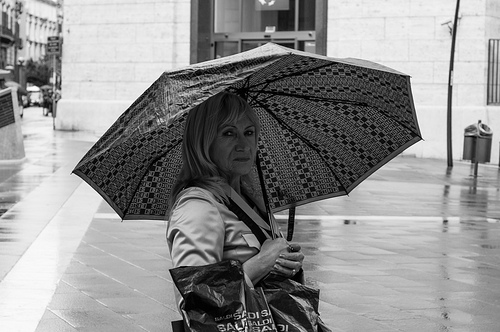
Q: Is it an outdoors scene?
A: Yes, it is outdoors.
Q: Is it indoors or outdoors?
A: It is outdoors.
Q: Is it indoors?
A: No, it is outdoors.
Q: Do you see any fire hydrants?
A: No, there are no fire hydrants.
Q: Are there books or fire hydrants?
A: No, there are no fire hydrants or books.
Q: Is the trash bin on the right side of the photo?
A: Yes, the trash bin is on the right of the image.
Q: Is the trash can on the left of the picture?
A: No, the trash can is on the right of the image.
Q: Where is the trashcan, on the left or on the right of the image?
A: The trashcan is on the right of the image.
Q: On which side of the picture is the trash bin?
A: The trash bin is on the right of the image.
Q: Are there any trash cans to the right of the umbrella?
A: Yes, there is a trash can to the right of the umbrella.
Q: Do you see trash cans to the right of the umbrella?
A: Yes, there is a trash can to the right of the umbrella.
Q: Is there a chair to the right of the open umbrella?
A: No, there is a trash can to the right of the umbrella.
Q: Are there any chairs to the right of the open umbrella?
A: No, there is a trash can to the right of the umbrella.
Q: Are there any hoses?
A: No, there are no hoses.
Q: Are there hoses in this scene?
A: No, there are no hoses.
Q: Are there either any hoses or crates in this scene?
A: No, there are no hoses or crates.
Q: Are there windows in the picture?
A: Yes, there is a window.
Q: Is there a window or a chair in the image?
A: Yes, there is a window.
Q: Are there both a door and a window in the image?
A: Yes, there are both a window and a door.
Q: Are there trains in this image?
A: No, there are no trains.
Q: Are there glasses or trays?
A: No, there are no glasses or trays.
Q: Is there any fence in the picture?
A: No, there are no fences.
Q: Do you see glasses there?
A: No, there are no glasses.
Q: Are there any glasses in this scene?
A: No, there are no glasses.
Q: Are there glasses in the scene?
A: No, there are no glasses.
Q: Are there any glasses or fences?
A: No, there are no glasses or fences.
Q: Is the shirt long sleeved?
A: Yes, the shirt is long sleeved.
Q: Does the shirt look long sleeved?
A: Yes, the shirt is long sleeved.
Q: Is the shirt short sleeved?
A: No, the shirt is long sleeved.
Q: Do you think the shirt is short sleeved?
A: No, the shirt is long sleeved.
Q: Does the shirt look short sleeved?
A: No, the shirt is long sleeved.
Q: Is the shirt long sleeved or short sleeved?
A: The shirt is long sleeved.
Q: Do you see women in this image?
A: Yes, there is a woman.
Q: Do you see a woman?
A: Yes, there is a woman.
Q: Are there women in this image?
A: Yes, there is a woman.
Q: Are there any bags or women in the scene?
A: Yes, there is a woman.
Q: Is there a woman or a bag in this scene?
A: Yes, there is a woman.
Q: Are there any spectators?
A: No, there are no spectators.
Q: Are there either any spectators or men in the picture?
A: No, there are no spectators or men.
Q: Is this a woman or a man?
A: This is a woman.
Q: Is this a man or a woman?
A: This is a woman.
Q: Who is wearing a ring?
A: The woman is wearing a ring.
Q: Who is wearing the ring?
A: The woman is wearing a ring.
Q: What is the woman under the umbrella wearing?
A: The woman is wearing a ring.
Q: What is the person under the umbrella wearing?
A: The woman is wearing a ring.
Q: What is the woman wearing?
A: The woman is wearing a ring.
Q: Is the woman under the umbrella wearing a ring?
A: Yes, the woman is wearing a ring.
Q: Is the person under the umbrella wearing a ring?
A: Yes, the woman is wearing a ring.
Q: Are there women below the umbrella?
A: Yes, there is a woman below the umbrella.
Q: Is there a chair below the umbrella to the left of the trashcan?
A: No, there is a woman below the umbrella.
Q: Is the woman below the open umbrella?
A: Yes, the woman is below the umbrella.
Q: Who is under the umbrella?
A: The woman is under the umbrella.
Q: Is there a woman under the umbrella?
A: Yes, there is a woman under the umbrella.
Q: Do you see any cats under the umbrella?
A: No, there is a woman under the umbrella.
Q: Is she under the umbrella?
A: Yes, the woman is under the umbrella.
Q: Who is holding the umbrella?
A: The woman is holding the umbrella.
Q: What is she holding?
A: The woman is holding the umbrella.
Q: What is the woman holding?
A: The woman is holding the umbrella.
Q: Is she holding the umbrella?
A: Yes, the woman is holding the umbrella.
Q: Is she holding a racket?
A: No, the woman is holding the umbrella.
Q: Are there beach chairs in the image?
A: No, there are no beach chairs.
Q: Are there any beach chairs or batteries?
A: No, there are no beach chairs or batteries.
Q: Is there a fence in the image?
A: No, there are no fences.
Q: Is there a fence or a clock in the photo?
A: No, there are no fences or clocks.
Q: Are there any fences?
A: No, there are no fences.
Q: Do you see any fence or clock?
A: No, there are no fences or clocks.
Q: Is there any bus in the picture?
A: No, there are no buses.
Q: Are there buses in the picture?
A: No, there are no buses.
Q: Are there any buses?
A: No, there are no buses.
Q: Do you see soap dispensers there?
A: No, there are no soap dispensers.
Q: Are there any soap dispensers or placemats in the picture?
A: No, there are no soap dispensers or placemats.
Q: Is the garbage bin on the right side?
A: Yes, the garbage bin is on the right of the image.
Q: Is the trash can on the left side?
A: No, the trash can is on the right of the image.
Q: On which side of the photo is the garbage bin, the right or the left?
A: The garbage bin is on the right of the image.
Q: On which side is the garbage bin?
A: The garbage bin is on the right of the image.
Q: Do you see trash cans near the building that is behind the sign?
A: Yes, there is a trash can near the building.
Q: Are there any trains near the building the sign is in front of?
A: No, there is a trash can near the building.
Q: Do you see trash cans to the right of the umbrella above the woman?
A: Yes, there is a trash can to the right of the umbrella.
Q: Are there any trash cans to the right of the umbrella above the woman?
A: Yes, there is a trash can to the right of the umbrella.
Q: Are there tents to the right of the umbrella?
A: No, there is a trash can to the right of the umbrella.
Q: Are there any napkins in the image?
A: No, there are no napkins.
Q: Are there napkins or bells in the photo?
A: No, there are no napkins or bells.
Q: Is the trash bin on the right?
A: Yes, the trash bin is on the right of the image.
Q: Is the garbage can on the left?
A: No, the garbage can is on the right of the image.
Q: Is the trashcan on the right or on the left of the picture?
A: The trashcan is on the right of the image.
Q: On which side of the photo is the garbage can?
A: The garbage can is on the right of the image.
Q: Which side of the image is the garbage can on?
A: The garbage can is on the right of the image.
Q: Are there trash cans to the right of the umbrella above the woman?
A: Yes, there is a trash can to the right of the umbrella.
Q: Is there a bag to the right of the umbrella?
A: No, there is a trash can to the right of the umbrella.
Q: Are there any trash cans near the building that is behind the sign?
A: Yes, there is a trash can near the building.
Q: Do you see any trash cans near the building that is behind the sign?
A: Yes, there is a trash can near the building.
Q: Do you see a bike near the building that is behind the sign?
A: No, there is a trash can near the building.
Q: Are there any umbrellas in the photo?
A: Yes, there is an umbrella.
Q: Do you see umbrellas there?
A: Yes, there is an umbrella.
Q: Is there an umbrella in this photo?
A: Yes, there is an umbrella.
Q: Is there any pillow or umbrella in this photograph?
A: Yes, there is an umbrella.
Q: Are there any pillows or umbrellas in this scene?
A: Yes, there is an umbrella.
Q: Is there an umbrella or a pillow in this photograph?
A: Yes, there is an umbrella.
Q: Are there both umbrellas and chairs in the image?
A: No, there is an umbrella but no chairs.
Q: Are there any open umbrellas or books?
A: Yes, there is an open umbrella.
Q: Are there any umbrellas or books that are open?
A: Yes, the umbrella is open.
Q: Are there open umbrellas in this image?
A: Yes, there is an open umbrella.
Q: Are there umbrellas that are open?
A: Yes, there is an umbrella that is open.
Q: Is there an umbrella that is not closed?
A: Yes, there is a open umbrella.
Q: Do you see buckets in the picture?
A: No, there are no buckets.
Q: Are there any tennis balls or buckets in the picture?
A: No, there are no buckets or tennis balls.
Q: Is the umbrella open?
A: Yes, the umbrella is open.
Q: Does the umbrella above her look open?
A: Yes, the umbrella is open.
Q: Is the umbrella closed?
A: No, the umbrella is open.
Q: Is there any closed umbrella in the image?
A: No, there is an umbrella but it is open.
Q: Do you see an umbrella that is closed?
A: No, there is an umbrella but it is open.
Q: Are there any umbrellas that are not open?
A: No, there is an umbrella but it is open.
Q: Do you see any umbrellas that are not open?
A: No, there is an umbrella but it is open.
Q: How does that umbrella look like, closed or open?
A: The umbrella is open.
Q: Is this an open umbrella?
A: Yes, this is an open umbrella.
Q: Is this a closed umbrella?
A: No, this is an open umbrella.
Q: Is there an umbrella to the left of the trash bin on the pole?
A: Yes, there is an umbrella to the left of the garbage bin.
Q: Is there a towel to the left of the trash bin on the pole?
A: No, there is an umbrella to the left of the trash can.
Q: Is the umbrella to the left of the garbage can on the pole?
A: Yes, the umbrella is to the left of the trash bin.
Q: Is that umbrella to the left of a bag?
A: No, the umbrella is to the left of the trash bin.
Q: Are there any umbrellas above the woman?
A: Yes, there is an umbrella above the woman.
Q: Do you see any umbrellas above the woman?
A: Yes, there is an umbrella above the woman.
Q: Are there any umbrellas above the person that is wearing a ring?
A: Yes, there is an umbrella above the woman.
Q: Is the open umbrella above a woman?
A: Yes, the umbrella is above a woman.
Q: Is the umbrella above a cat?
A: No, the umbrella is above a woman.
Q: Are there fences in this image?
A: No, there are no fences.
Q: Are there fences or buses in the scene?
A: No, there are no fences or buses.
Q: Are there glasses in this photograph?
A: No, there are no glasses.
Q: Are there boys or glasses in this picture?
A: No, there are no glasses or boys.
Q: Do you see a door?
A: Yes, there are doors.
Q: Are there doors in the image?
A: Yes, there are doors.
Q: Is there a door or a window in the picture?
A: Yes, there are doors.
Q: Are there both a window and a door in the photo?
A: Yes, there are both a door and a window.